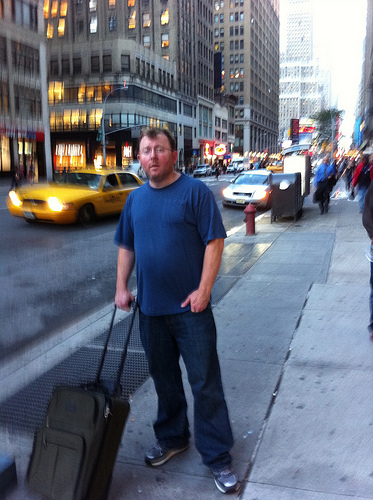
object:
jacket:
[310, 171, 339, 204]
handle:
[95, 291, 140, 394]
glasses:
[136, 146, 171, 155]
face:
[138, 131, 173, 180]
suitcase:
[26, 323, 127, 500]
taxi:
[5, 169, 145, 225]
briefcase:
[312, 189, 320, 204]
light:
[47, 196, 64, 213]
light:
[7, 190, 22, 206]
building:
[212, 0, 283, 161]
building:
[275, 0, 335, 145]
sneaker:
[145, 442, 189, 469]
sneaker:
[207, 466, 240, 497]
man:
[111, 124, 239, 494]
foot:
[142, 440, 187, 464]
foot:
[210, 448, 241, 497]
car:
[220, 169, 274, 211]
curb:
[0, 205, 273, 371]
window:
[71, 53, 83, 77]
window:
[54, 79, 63, 102]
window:
[93, 148, 104, 171]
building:
[44, 0, 218, 181]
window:
[119, 51, 131, 76]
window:
[158, 7, 169, 27]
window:
[141, 12, 151, 30]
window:
[106, 12, 118, 33]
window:
[55, 20, 67, 36]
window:
[160, 34, 170, 47]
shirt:
[111, 174, 225, 315]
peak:
[145, 129, 167, 139]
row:
[2, 2, 333, 169]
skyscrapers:
[2, 2, 334, 176]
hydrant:
[242, 200, 258, 237]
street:
[0, 139, 243, 344]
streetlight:
[276, 131, 350, 152]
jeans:
[135, 303, 238, 466]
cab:
[0, 160, 143, 240]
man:
[335, 164, 360, 239]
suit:
[312, 163, 337, 217]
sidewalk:
[302, 207, 348, 497]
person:
[348, 158, 360, 201]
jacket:
[345, 166, 357, 186]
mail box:
[264, 170, 308, 229]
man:
[298, 153, 343, 218]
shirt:
[315, 164, 333, 185]